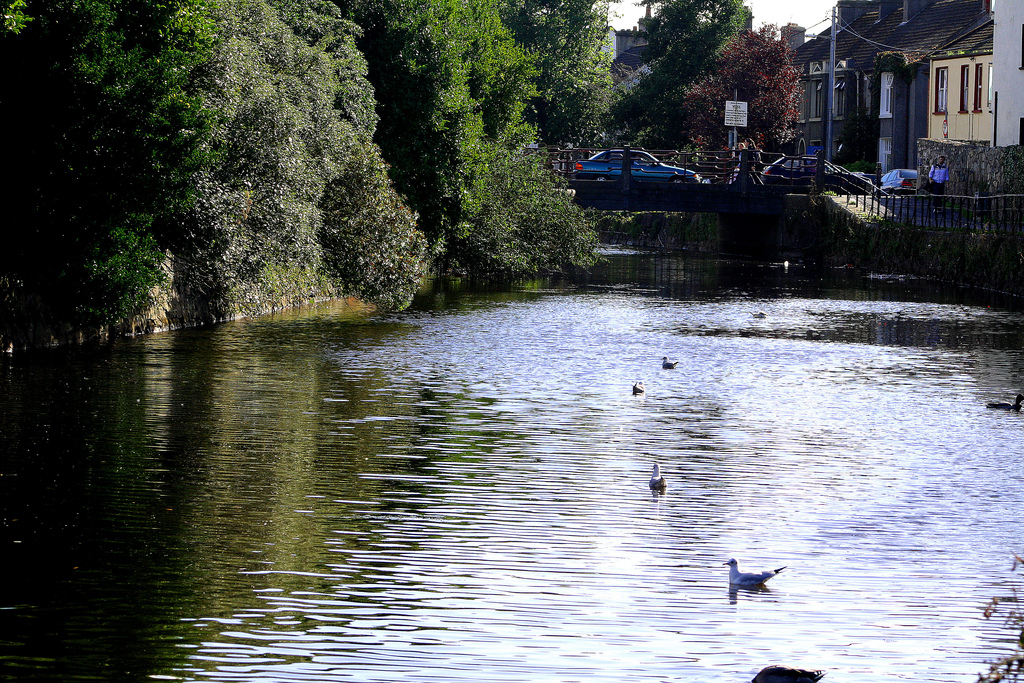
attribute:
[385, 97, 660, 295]
leaves — green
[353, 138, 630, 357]
leaves — green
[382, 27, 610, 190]
leaves — green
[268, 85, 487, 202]
leaves — green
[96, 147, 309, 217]
leaves — green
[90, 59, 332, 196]
leaves — green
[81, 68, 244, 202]
leaves — green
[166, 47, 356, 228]
leaves — green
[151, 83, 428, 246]
leaves — green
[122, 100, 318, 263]
leaves — green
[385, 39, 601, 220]
leaves — green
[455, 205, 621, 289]
leaves — green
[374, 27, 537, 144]
leaves — green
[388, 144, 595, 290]
leaves — green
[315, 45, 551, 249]
leaves — green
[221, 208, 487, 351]
leaves — green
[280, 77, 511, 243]
leaves — green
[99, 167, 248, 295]
leaves — green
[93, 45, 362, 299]
leaves — green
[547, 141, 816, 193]
fence — metal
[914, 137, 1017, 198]
wall — stone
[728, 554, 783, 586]
bird — swimming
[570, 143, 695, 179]
car — blue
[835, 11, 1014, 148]
house — yellow